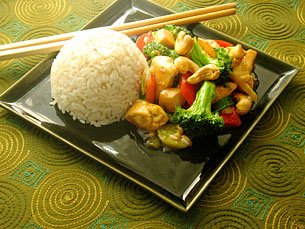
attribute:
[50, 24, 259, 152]
meal — cooked, asian, great, flavorful, special, nice, hot, delicious, tasty, some, chinese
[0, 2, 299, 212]
plate — matallic, black, square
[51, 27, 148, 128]
rice — big, white, cooked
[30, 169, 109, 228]
shapes — circlular, gold, round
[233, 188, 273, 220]
lines — blue, little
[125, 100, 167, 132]
chicken — fried, cooked, cubed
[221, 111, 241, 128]
pepper — sliced, red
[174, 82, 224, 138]
brocolii — green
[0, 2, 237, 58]
chop stick — brown, wooden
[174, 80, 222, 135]
broccili — green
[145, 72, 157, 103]
carrot — sliced, orange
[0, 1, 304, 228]
cloth — green